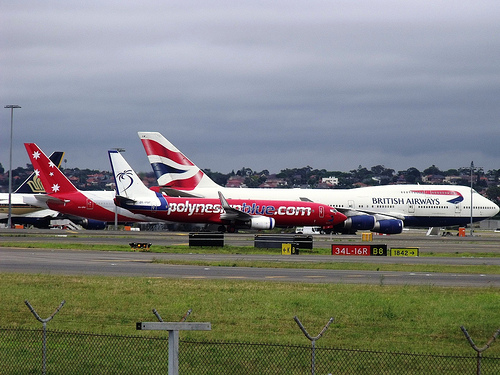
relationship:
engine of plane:
[336, 213, 413, 236] [296, 154, 471, 274]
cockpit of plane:
[325, 206, 340, 213] [107, 147, 347, 232]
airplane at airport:
[108, 150, 346, 233] [0, 1, 498, 373]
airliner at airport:
[20, 132, 499, 238] [0, 1, 498, 373]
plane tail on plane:
[103, 147, 152, 205] [100, 147, 350, 242]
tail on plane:
[135, 129, 223, 190] [137, 130, 499, 227]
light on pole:
[3, 102, 22, 109] [6, 107, 14, 227]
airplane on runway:
[108, 150, 346, 233] [395, 221, 463, 263]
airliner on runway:
[20, 132, 499, 238] [395, 221, 463, 263]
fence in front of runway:
[1, 293, 499, 373] [1, 217, 499, 294]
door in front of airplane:
[317, 205, 324, 217] [133, 127, 498, 244]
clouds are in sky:
[0, 0, 500, 169] [137, 33, 238, 95]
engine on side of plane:
[249, 214, 276, 229] [137, 130, 499, 227]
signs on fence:
[331, 240, 423, 254] [58, 235, 488, 256]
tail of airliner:
[137, 129, 223, 191] [20, 132, 499, 238]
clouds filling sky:
[87, 27, 362, 125] [1, 3, 499, 175]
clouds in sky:
[0, 0, 500, 169] [328, 46, 432, 103]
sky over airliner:
[328, 46, 432, 103] [20, 132, 499, 238]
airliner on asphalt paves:
[20, 132, 499, 238] [0, 254, 498, 286]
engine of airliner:
[343, 213, 404, 234] [20, 132, 499, 238]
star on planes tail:
[49, 183, 60, 190] [20, 138, 77, 193]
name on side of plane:
[371, 196, 441, 206] [137, 130, 499, 227]